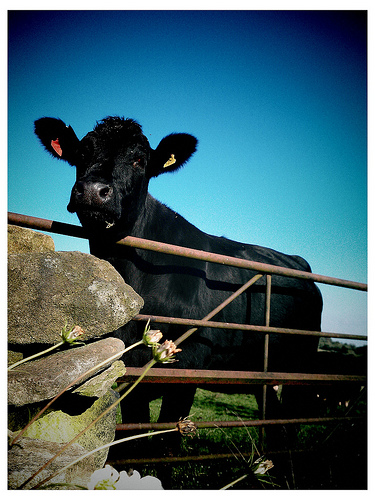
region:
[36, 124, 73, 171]
red tag in cows ear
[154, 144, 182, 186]
yellow tag in cows ear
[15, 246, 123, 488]
pile of boulders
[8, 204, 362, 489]
rusty iron gate keeping cow in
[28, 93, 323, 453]
beautiful curious black cow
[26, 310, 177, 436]
flowers are facing the sun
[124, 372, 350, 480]
green pasture behind the cow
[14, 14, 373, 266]
bright blue clear sky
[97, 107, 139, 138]
cow has black tuft of fur on forehead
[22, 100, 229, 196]
ears have fluffy fur and stand upright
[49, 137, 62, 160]
Red tag in the cows right ear.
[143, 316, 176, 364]
The tops of two very close flowers.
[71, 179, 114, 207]
Black shiny nose of a large black cow.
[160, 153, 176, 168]
Yellow tag in a black cows left ear.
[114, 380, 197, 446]
Two front black legs of a cow.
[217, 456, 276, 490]
The lowest flower to the ground.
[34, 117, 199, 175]
Right and left ears of a black cow.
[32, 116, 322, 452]
Black cow standing at a metal gate.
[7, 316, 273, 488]
Five flowers all leaning to the right.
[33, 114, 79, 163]
Right ear of a black cow with a red tag inside it.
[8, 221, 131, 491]
pile of stacked rocks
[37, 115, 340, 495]
Black cow in field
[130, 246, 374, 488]
rusty brown fence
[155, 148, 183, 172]
yellow tag on ear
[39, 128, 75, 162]
red tag on cow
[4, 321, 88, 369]
Pink flower laying on rock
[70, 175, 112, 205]
shiny black cow's nose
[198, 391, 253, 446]
green grass in pasture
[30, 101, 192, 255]
cow looking over fence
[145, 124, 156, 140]
fly flying around cow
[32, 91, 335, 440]
black cow near brown fence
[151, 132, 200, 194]
yellow tag in left ear of black cow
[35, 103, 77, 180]
red tag in right ear of black cow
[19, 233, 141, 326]
gray and white rock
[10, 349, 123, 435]
gray and white rock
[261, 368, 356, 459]
brown fence in field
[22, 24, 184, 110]
blue sky without clouds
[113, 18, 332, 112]
blue sky without clouds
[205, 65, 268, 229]
blue sky without clouds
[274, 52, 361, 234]
blue sky without clouds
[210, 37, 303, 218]
blue sky without clouds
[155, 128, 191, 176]
yellow tag in left ear of black cow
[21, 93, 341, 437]
black cow in field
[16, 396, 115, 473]
gray and white rock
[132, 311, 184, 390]
green and pink flowers near fence